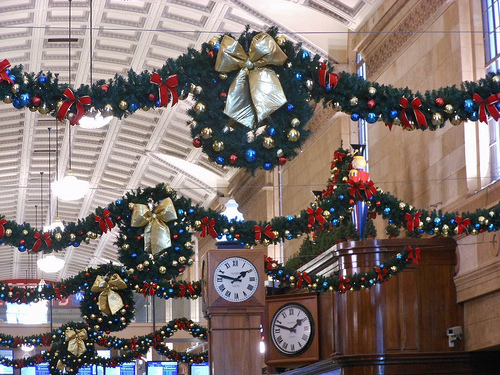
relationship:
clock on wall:
[263, 294, 321, 363] [208, 300, 265, 373]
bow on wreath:
[213, 31, 288, 131] [1, 55, 218, 148]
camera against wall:
[438, 318, 468, 354] [444, 226, 498, 356]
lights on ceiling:
[29, 99, 116, 276] [2, 1, 170, 59]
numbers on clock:
[213, 254, 252, 298] [268, 301, 316, 356]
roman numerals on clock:
[287, 304, 297, 318] [268, 301, 316, 356]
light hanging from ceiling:
[78, 109, 115, 131] [2, 0, 391, 300]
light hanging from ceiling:
[48, 170, 96, 202] [2, 0, 391, 300]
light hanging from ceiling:
[34, 249, 66, 275] [2, 0, 391, 300]